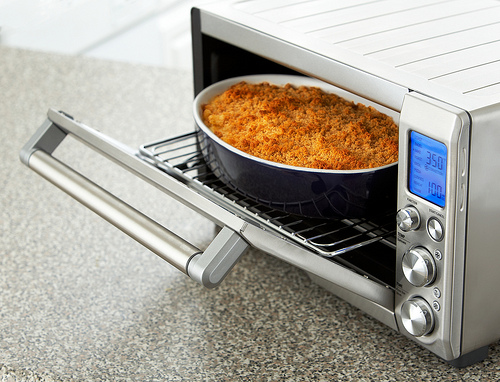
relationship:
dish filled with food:
[189, 75, 402, 212] [236, 102, 364, 154]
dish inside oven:
[189, 75, 402, 212] [46, 2, 499, 368]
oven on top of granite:
[46, 2, 499, 368] [18, 285, 322, 377]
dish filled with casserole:
[189, 75, 402, 212] [236, 102, 364, 154]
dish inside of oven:
[189, 75, 402, 212] [46, 2, 499, 368]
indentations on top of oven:
[338, 7, 473, 52] [46, 2, 499, 368]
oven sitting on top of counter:
[46, 2, 499, 368] [18, 285, 322, 377]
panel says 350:
[406, 126, 447, 206] [422, 153, 444, 169]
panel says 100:
[406, 126, 447, 206] [422, 179, 445, 196]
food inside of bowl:
[236, 102, 364, 154] [189, 75, 402, 212]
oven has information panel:
[46, 2, 499, 368] [401, 129, 451, 206]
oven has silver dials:
[46, 2, 499, 368] [393, 208, 437, 342]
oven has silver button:
[46, 2, 499, 368] [424, 218, 443, 244]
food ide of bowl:
[236, 102, 364, 154] [189, 75, 402, 212]